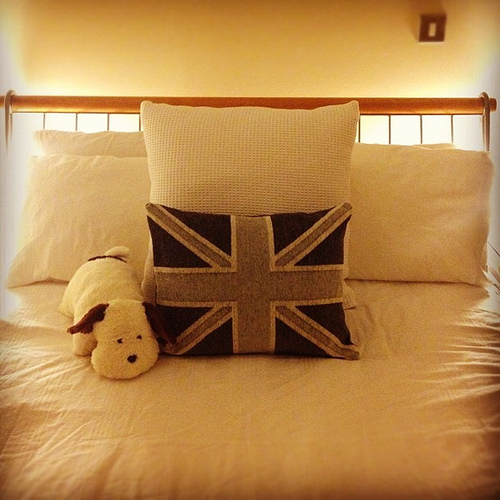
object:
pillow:
[145, 201, 363, 361]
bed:
[0, 88, 500, 500]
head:
[66, 299, 177, 380]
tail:
[104, 246, 133, 258]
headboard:
[1, 90, 497, 156]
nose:
[126, 354, 137, 364]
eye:
[116, 338, 123, 344]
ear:
[66, 303, 109, 336]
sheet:
[0, 241, 500, 500]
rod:
[479, 91, 491, 150]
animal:
[56, 245, 177, 380]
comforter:
[6, 129, 494, 288]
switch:
[419, 13, 449, 43]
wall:
[0, 0, 500, 154]